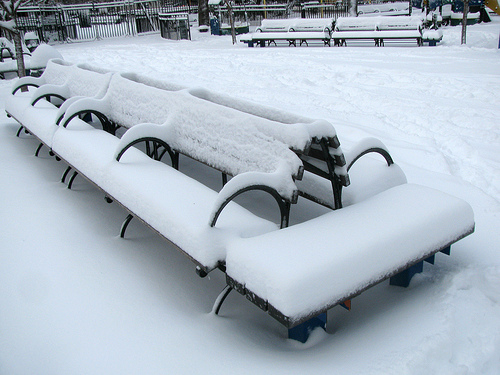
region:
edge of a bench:
[290, 318, 300, 347]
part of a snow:
[62, 250, 63, 252]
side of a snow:
[319, 320, 320, 322]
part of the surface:
[138, 298, 165, 325]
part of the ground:
[40, 260, 102, 287]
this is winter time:
[22, 75, 387, 307]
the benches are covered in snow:
[60, 84, 412, 309]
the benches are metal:
[135, 129, 345, 236]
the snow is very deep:
[112, 161, 414, 347]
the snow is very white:
[22, 241, 173, 358]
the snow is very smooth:
[7, 236, 147, 369]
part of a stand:
[211, 271, 243, 323]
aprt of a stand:
[212, 271, 244, 324]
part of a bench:
[289, 258, 335, 349]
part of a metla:
[202, 275, 214, 298]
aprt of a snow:
[326, 203, 348, 241]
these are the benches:
[152, 95, 322, 237]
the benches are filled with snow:
[189, 104, 356, 241]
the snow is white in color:
[305, 211, 379, 276]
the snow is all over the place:
[51, 274, 171, 373]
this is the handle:
[198, 166, 280, 220]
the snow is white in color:
[30, 270, 160, 370]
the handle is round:
[202, 175, 270, 218]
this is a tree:
[6, 21, 21, 56]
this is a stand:
[161, 12, 191, 34]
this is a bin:
[212, 12, 233, 29]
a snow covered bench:
[70, 24, 407, 271]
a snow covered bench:
[98, 81, 363, 370]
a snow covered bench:
[153, 118, 392, 308]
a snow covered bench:
[151, 38, 476, 358]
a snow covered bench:
[224, 183, 467, 340]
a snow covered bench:
[129, 101, 299, 311]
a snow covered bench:
[21, 60, 158, 200]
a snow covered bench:
[192, 84, 405, 211]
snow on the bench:
[127, 128, 241, 249]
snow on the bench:
[281, 73, 372, 201]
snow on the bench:
[120, 58, 220, 118]